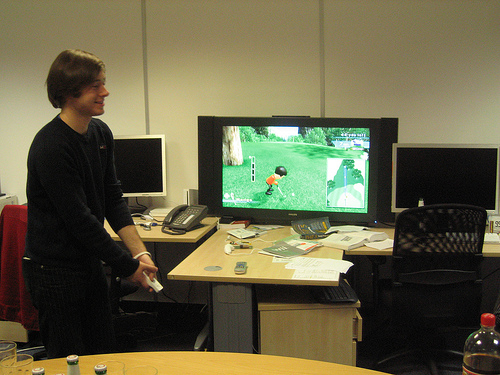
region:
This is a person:
[17, 26, 189, 351]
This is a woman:
[14, 23, 181, 363]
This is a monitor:
[112, 132, 176, 204]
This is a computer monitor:
[101, 130, 173, 200]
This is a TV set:
[193, 112, 400, 229]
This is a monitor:
[388, 137, 497, 224]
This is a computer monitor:
[385, 137, 496, 215]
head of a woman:
[27, 23, 122, 137]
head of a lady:
[44, 35, 116, 132]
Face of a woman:
[89, 56, 118, 121]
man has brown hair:
[57, 18, 107, 85]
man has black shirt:
[32, 112, 138, 251]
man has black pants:
[47, 231, 167, 356]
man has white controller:
[122, 259, 174, 294]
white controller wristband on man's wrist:
[127, 236, 157, 263]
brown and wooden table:
[207, 207, 332, 287]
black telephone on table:
[144, 205, 214, 235]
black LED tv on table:
[172, 103, 378, 223]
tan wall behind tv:
[151, 3, 317, 97]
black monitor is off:
[111, 128, 171, 193]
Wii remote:
[115, 235, 174, 304]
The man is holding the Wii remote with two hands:
[90, 205, 179, 305]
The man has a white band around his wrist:
[117, 232, 157, 262]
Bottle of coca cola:
[449, 286, 498, 371]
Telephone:
[152, 190, 211, 237]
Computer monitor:
[117, 121, 174, 226]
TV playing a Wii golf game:
[204, 115, 380, 215]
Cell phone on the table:
[228, 257, 253, 283]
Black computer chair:
[388, 192, 498, 315]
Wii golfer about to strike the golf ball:
[254, 153, 299, 205]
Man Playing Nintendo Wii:
[26, 47, 173, 347]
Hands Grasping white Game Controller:
[123, 245, 173, 309]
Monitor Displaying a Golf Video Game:
[195, 111, 398, 233]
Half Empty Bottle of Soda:
[435, 289, 498, 374]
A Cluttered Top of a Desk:
[194, 220, 411, 288]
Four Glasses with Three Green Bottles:
[1, 340, 162, 373]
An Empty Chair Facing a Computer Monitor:
[391, 140, 498, 314]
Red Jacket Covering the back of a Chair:
[1, 191, 43, 340]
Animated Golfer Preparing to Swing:
[240, 151, 323, 208]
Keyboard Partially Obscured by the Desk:
[280, 256, 384, 317]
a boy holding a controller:
[7, 37, 190, 364]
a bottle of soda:
[452, 300, 499, 374]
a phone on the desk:
[101, 196, 221, 245]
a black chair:
[361, 197, 499, 371]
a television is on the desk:
[166, 104, 498, 286]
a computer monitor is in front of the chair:
[359, 131, 495, 373]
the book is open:
[315, 222, 389, 253]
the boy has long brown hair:
[37, 44, 120, 139]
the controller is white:
[123, 255, 164, 297]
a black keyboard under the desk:
[260, 254, 360, 313]